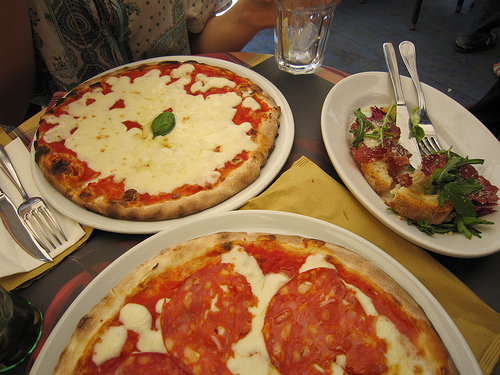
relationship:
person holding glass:
[1, 0, 274, 128] [274, 1, 340, 76]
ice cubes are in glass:
[281, 7, 320, 66] [274, 1, 340, 76]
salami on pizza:
[263, 266, 386, 373] [50, 230, 460, 373]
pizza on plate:
[50, 230, 460, 373] [27, 209, 486, 374]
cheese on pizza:
[67, 74, 238, 196] [36, 59, 279, 220]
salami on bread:
[355, 106, 409, 161] [350, 104, 464, 228]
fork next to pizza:
[0, 142, 69, 251] [36, 59, 279, 220]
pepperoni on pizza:
[160, 263, 388, 374] [50, 230, 460, 373]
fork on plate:
[400, 39, 455, 156] [319, 68, 499, 258]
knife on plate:
[379, 41, 423, 176] [319, 68, 499, 258]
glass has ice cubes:
[274, 1, 340, 76] [281, 7, 320, 66]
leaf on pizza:
[149, 110, 178, 140] [36, 59, 279, 220]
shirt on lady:
[26, 0, 234, 88] [1, 0, 274, 128]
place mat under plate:
[245, 156, 499, 374] [27, 209, 486, 374]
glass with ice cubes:
[274, 1, 340, 76] [281, 7, 320, 66]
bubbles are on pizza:
[35, 145, 83, 191] [36, 59, 279, 220]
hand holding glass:
[236, 2, 279, 28] [274, 1, 340, 76]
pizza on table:
[50, 230, 460, 373] [1, 51, 499, 372]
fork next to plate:
[0, 142, 69, 251] [31, 53, 299, 235]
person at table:
[1, 0, 274, 128] [1, 51, 499, 372]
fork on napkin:
[0, 142, 69, 251] [1, 137, 88, 277]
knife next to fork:
[379, 41, 423, 176] [400, 39, 455, 156]